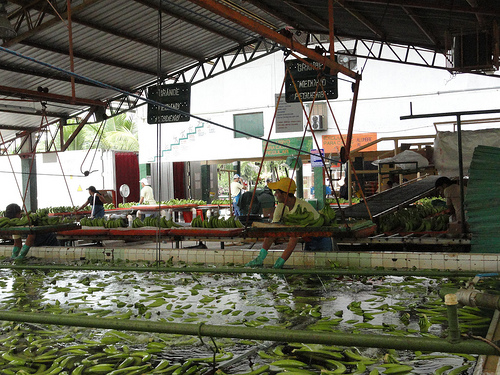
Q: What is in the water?
A: Bananas.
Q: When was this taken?
A: During the day.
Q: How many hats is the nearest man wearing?
A: One.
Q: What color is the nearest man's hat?
A: Yellow.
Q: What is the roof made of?
A: Metal.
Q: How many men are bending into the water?
A: Two.